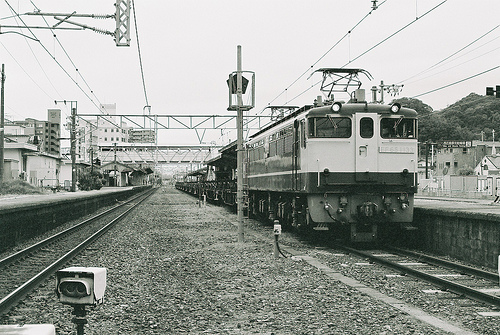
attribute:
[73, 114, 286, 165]
bridge — metal, small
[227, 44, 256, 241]
pole — metal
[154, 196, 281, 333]
gravel — grey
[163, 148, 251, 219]
car — empty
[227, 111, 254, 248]
pole — tall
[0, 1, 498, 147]
sky — overcast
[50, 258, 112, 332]
viewfinder — old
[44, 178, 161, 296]
train tracks — long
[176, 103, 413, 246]
locomotive — old style